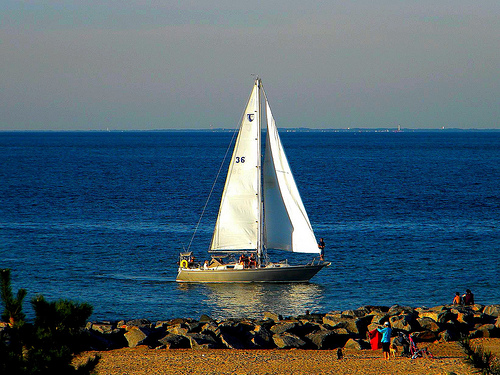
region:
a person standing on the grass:
[372, 315, 394, 355]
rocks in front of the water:
[65, 290, 492, 333]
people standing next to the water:
[446, 284, 475, 304]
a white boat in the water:
[178, 75, 327, 277]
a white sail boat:
[185, 73, 330, 278]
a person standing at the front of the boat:
[315, 233, 326, 260]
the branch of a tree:
[8, 278, 112, 374]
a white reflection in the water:
[196, 285, 318, 304]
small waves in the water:
[45, 169, 162, 219]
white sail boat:
[160, 49, 312, 277]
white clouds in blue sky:
[34, 15, 98, 72]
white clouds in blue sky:
[17, 48, 64, 76]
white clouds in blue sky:
[85, 21, 103, 53]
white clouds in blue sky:
[71, 32, 121, 104]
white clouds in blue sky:
[130, 25, 168, 63]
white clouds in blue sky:
[381, 41, 436, 78]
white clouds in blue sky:
[328, 52, 398, 110]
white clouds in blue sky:
[274, 19, 322, 43]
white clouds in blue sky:
[190, 9, 247, 44]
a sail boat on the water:
[145, 63, 358, 337]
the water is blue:
[333, 179, 428, 244]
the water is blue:
[334, 203, 427, 285]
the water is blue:
[71, 200, 168, 251]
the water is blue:
[41, 182, 163, 302]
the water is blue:
[345, 125, 445, 240]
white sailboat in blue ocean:
[185, 73, 317, 307]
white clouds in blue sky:
[12, 1, 70, 46]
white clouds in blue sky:
[72, 62, 119, 97]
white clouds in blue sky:
[184, 62, 209, 92]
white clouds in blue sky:
[101, 52, 161, 86]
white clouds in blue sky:
[390, 35, 448, 57]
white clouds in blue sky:
[407, 9, 444, 53]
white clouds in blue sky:
[347, 28, 407, 59]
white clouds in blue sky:
[328, 23, 390, 68]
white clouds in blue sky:
[217, 21, 297, 59]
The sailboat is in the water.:
[1, 0, 499, 329]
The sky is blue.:
[1, 0, 499, 134]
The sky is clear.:
[1, 1, 499, 136]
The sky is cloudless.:
[1, 1, 498, 136]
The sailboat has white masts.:
[166, 70, 361, 289]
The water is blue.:
[2, 125, 498, 325]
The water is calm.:
[2, 120, 499, 314]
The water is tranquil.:
[0, 123, 499, 331]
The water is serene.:
[1, 120, 499, 322]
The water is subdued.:
[1, 119, 498, 332]